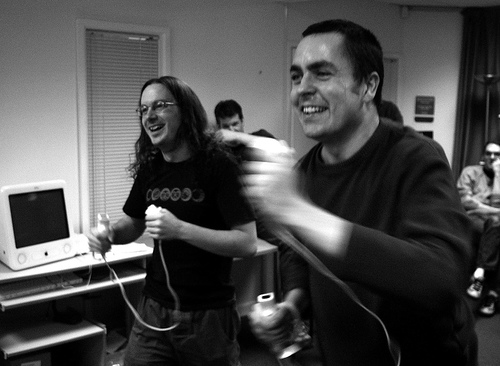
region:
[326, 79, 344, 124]
part of a cheel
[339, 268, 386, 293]
part of a han d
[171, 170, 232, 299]
pat of a hand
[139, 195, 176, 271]
part of a fist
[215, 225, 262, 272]
part of an elbow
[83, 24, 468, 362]
Two people playing wii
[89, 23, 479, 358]
The men are holding wii controllers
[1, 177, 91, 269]
Computer on the desk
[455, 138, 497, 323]
The man is sitting down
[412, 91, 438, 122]
Black sign on the wall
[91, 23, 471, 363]
The men are standing next to each other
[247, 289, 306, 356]
The controller is white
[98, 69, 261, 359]
The man is holding two controllers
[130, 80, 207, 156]
The man is wearing glasses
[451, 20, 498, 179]
Curtains behind the man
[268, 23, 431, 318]
this is a man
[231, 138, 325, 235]
this is the hand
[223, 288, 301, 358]
the hand is holding a remote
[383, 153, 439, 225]
this is a t shirt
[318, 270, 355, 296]
this is a cable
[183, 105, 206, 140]
this is the hair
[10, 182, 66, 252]
this is a monitor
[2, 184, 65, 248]
then monitor is off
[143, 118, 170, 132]
the man is smiling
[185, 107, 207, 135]
the hair is long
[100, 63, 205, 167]
a man with eyeglasses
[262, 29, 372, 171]
the man is smiling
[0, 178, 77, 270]
an Apple eMac computer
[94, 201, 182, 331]
a Wii video game controller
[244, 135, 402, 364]
a Wii video game controller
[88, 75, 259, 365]
a man playing a video game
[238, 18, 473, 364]
a man playing a video game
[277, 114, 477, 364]
a man's black t-shirt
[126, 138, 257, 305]
a man's black t-shirt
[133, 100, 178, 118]
a pair of eyeglasses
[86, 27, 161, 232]
white venetian blinds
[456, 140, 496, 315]
a man sitting with legs crossed